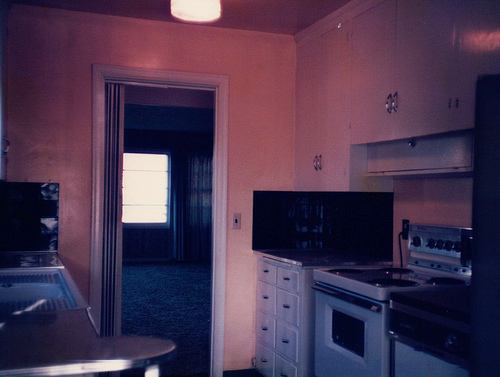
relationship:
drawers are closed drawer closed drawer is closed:
[255, 255, 304, 376] [275, 264, 303, 292]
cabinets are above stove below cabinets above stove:
[292, 0, 500, 191] [294, 0, 500, 376]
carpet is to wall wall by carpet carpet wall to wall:
[121, 224, 210, 375] [121, 264, 210, 376]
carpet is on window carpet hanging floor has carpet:
[169, 139, 210, 263] [121, 264, 210, 376]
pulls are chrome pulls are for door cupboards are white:
[385, 91, 399, 113] [292, 0, 500, 191]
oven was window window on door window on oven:
[314, 223, 471, 376] [325, 303, 367, 364]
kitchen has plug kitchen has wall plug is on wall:
[396, 219, 408, 238] [401, 220, 410, 240]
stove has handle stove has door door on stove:
[314, 223, 471, 376] [315, 280, 389, 373]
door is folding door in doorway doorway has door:
[104, 84, 120, 336] [92, 64, 224, 376]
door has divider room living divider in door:
[92, 64, 224, 376] [104, 84, 120, 336]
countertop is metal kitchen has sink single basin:
[0, 264, 177, 373] [0, 261, 91, 325]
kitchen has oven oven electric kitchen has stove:
[314, 223, 471, 376] [316, 266, 473, 300]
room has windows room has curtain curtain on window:
[121, 152, 167, 224] [169, 139, 210, 263]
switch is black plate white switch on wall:
[235, 219, 238, 224] [233, 212, 242, 230]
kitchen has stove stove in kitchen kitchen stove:
[316, 266, 473, 300] [314, 223, 471, 376]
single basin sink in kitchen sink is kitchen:
[0, 261, 91, 325] [0, 2, 497, 376]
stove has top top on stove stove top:
[314, 223, 471, 376] [316, 266, 473, 300]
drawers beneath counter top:
[252, 255, 298, 375] [250, 239, 398, 272]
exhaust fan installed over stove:
[353, 130, 482, 182] [299, 216, 472, 375]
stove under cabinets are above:
[308, 219, 477, 374] [292, 17, 358, 191]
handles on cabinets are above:
[382, 90, 400, 111] [292, 17, 358, 191]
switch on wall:
[227, 212, 243, 236] [0, 0, 305, 374]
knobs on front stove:
[406, 232, 460, 253] [308, 219, 477, 374]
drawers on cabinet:
[249, 252, 303, 373] [248, 245, 391, 375]